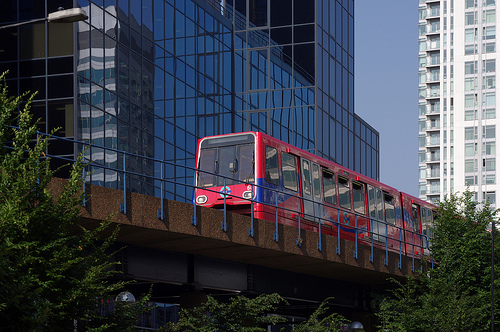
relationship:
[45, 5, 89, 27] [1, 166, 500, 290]
light over tracks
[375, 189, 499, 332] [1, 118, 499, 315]
trees below overpass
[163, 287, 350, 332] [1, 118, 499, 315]
trees below overpass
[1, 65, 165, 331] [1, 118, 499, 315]
trees below overpass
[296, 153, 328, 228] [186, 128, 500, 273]
doors on train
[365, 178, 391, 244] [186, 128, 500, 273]
doors on train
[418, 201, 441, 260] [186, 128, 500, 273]
doors on train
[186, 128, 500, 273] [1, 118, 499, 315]
train crossing overpass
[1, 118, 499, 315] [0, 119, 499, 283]
overpass with rails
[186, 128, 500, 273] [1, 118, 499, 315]
train across overpass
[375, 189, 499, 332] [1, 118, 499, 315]
trees surround overpass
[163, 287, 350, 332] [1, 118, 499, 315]
trees surround overpass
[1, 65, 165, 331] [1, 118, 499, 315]
trees surround overpass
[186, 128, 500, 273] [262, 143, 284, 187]
train with windows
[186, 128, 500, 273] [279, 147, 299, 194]
train with windows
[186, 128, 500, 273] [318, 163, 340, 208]
train with windows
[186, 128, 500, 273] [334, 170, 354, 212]
train with windows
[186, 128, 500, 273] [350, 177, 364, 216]
train with windows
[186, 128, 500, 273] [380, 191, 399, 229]
train with windows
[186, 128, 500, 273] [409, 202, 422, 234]
train with windows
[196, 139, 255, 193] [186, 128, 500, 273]
windshield of train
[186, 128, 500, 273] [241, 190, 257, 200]
train has lights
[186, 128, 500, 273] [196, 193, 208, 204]
train has lights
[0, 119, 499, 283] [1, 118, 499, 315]
rails of overpass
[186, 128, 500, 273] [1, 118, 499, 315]
train on overpass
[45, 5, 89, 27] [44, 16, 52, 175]
light on pole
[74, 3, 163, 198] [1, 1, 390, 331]
reflection in building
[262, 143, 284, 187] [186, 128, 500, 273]
windows on train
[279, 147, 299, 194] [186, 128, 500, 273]
windows on train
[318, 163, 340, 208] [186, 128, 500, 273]
windows on train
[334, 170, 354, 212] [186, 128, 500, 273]
windows on train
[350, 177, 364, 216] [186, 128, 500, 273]
windows on train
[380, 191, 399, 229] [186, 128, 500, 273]
windows on train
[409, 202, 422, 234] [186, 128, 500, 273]
windows on train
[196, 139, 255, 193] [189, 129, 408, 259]
windshield on car